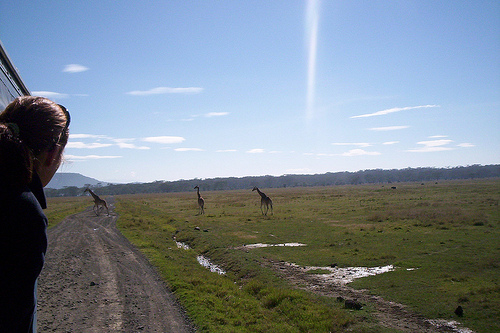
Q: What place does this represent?
A: It represents the field.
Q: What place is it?
A: It is a field.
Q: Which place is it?
A: It is a field.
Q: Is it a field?
A: Yes, it is a field.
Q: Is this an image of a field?
A: Yes, it is showing a field.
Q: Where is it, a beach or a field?
A: It is a field.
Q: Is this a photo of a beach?
A: No, the picture is showing a field.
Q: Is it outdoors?
A: Yes, it is outdoors.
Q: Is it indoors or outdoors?
A: It is outdoors.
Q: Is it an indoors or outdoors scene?
A: It is outdoors.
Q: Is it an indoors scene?
A: No, it is outdoors.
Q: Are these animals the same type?
A: Yes, all the animals are giraffes.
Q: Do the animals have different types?
A: No, all the animals are giraffes.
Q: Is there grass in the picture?
A: Yes, there is grass.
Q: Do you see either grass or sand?
A: Yes, there is grass.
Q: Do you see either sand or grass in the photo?
A: Yes, there is grass.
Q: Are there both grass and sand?
A: No, there is grass but no sand.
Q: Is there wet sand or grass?
A: Yes, there is wet grass.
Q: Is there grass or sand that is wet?
A: Yes, the grass is wet.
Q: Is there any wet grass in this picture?
A: Yes, there is wet grass.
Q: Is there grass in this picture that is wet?
A: Yes, there is grass that is wet.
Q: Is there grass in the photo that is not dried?
A: Yes, there is wet grass.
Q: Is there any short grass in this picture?
A: Yes, there is short grass.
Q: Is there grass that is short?
A: Yes, there is grass that is short.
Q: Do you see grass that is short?
A: Yes, there is grass that is short.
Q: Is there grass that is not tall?
A: Yes, there is short grass.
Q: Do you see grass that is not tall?
A: Yes, there is short grass.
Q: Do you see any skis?
A: No, there are no skis.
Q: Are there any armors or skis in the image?
A: No, there are no skis or armors.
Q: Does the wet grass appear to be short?
A: Yes, the grass is short.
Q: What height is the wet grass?
A: The grass is short.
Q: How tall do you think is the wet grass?
A: The grass is short.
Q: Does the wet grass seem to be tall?
A: No, the grass is short.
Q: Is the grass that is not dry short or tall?
A: The grass is short.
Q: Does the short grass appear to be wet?
A: Yes, the grass is wet.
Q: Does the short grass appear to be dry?
A: No, the grass is wet.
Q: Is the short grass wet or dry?
A: The grass is wet.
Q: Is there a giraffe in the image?
A: Yes, there is a giraffe.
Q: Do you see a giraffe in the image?
A: Yes, there is a giraffe.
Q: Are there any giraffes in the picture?
A: Yes, there is a giraffe.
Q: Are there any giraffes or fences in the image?
A: Yes, there is a giraffe.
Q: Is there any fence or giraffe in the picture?
A: Yes, there is a giraffe.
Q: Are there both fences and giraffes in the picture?
A: No, there is a giraffe but no fences.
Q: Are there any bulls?
A: No, there are no bulls.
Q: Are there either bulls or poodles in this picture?
A: No, there are no bulls or poodles.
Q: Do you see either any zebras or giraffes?
A: Yes, there is a giraffe.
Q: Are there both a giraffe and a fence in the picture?
A: No, there is a giraffe but no fences.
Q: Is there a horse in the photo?
A: No, there are no horses.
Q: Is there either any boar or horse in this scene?
A: No, there are no horses or boars.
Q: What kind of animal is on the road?
A: The animal is a giraffe.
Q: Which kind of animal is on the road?
A: The animal is a giraffe.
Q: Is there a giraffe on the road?
A: Yes, there is a giraffe on the road.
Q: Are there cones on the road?
A: No, there is a giraffe on the road.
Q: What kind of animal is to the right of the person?
A: The animal is a giraffe.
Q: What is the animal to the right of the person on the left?
A: The animal is a giraffe.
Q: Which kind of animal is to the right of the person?
A: The animal is a giraffe.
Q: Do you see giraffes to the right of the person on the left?
A: Yes, there is a giraffe to the right of the person.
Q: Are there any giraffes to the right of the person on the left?
A: Yes, there is a giraffe to the right of the person.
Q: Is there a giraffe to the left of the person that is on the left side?
A: No, the giraffe is to the right of the person.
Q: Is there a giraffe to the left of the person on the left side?
A: No, the giraffe is to the right of the person.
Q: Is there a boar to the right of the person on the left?
A: No, there is a giraffe to the right of the person.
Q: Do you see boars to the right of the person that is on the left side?
A: No, there is a giraffe to the right of the person.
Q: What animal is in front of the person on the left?
A: The giraffe is in front of the person.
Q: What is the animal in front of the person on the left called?
A: The animal is a giraffe.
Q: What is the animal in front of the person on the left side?
A: The animal is a giraffe.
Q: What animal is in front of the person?
A: The animal is a giraffe.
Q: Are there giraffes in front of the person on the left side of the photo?
A: Yes, there is a giraffe in front of the person.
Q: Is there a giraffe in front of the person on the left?
A: Yes, there is a giraffe in front of the person.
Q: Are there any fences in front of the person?
A: No, there is a giraffe in front of the person.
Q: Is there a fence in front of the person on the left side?
A: No, there is a giraffe in front of the person.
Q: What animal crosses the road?
A: The animal is a giraffe.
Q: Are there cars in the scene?
A: No, there are no cars.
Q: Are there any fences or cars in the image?
A: No, there are no cars or fences.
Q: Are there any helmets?
A: No, there are no helmets.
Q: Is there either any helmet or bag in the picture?
A: No, there are no helmets or bags.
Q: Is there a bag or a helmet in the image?
A: No, there are no helmets or bags.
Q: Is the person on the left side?
A: Yes, the person is on the left of the image.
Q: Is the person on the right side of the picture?
A: No, the person is on the left of the image.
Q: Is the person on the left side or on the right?
A: The person is on the left of the image.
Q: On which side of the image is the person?
A: The person is on the left of the image.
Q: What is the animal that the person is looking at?
A: The animal is a giraffe.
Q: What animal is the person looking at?
A: The person is looking at the giraffe.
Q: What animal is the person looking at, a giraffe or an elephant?
A: The person is looking at a giraffe.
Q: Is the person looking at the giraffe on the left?
A: Yes, the person is looking at the giraffe.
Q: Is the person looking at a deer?
A: No, the person is looking at the giraffe.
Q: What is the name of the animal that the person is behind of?
A: The animal is a giraffe.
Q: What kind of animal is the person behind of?
A: The person is behind the giraffe.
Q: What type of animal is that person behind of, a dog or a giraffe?
A: The person is behind a giraffe.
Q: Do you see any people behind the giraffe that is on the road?
A: Yes, there is a person behind the giraffe.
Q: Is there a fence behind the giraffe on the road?
A: No, there is a person behind the giraffe.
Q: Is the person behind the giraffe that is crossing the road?
A: Yes, the person is behind the giraffe.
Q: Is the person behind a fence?
A: No, the person is behind the giraffe.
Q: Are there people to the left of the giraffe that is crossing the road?
A: Yes, there is a person to the left of the giraffe.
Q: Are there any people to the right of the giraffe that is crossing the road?
A: No, the person is to the left of the giraffe.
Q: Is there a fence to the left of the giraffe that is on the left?
A: No, there is a person to the left of the giraffe.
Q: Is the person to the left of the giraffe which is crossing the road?
A: Yes, the person is to the left of the giraffe.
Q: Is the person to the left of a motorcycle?
A: No, the person is to the left of the giraffe.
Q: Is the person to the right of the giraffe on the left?
A: No, the person is to the left of the giraffe.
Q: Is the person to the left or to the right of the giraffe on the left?
A: The person is to the left of the giraffe.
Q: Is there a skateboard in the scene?
A: No, there are no skateboards.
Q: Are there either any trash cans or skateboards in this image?
A: No, there are no skateboards or trash cans.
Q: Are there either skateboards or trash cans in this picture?
A: No, there are no skateboards or trash cans.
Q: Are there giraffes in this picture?
A: Yes, there are giraffes.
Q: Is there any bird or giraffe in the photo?
A: Yes, there are giraffes.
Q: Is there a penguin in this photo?
A: No, there are no penguins.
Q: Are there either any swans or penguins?
A: No, there are no penguins or swans.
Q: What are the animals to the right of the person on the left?
A: The animals are giraffes.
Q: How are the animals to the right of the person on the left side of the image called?
A: The animals are giraffes.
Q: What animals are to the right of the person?
A: The animals are giraffes.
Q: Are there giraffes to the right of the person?
A: Yes, there are giraffes to the right of the person.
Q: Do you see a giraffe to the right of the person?
A: Yes, there are giraffes to the right of the person.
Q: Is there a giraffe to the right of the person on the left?
A: Yes, there are giraffes to the right of the person.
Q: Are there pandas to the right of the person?
A: No, there are giraffes to the right of the person.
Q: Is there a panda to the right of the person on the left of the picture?
A: No, there are giraffes to the right of the person.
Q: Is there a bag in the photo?
A: No, there are no bags.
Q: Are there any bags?
A: No, there are no bags.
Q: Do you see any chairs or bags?
A: No, there are no bags or chairs.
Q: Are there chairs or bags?
A: No, there are no bags or chairs.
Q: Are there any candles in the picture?
A: No, there are no candles.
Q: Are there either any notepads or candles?
A: No, there are no candles or notepads.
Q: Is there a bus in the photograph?
A: Yes, there is a bus.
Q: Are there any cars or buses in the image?
A: Yes, there is a bus.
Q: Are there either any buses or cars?
A: Yes, there is a bus.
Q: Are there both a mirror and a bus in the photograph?
A: No, there is a bus but no mirrors.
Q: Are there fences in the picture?
A: No, there are no fences.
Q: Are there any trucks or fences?
A: No, there are no fences or trucks.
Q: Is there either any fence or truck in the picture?
A: No, there are no fences or trucks.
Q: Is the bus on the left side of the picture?
A: Yes, the bus is on the left of the image.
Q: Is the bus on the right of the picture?
A: No, the bus is on the left of the image.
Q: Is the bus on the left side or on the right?
A: The bus is on the left of the image.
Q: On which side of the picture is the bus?
A: The bus is on the left of the image.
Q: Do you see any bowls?
A: No, there are no bowls.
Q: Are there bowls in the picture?
A: No, there are no bowls.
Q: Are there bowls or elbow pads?
A: No, there are no bowls or elbow pads.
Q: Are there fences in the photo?
A: No, there are no fences.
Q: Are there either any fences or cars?
A: No, there are no fences or cars.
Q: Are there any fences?
A: No, there are no fences.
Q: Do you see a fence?
A: No, there are no fences.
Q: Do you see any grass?
A: Yes, there is grass.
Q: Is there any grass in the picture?
A: Yes, there is grass.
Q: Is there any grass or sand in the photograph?
A: Yes, there is grass.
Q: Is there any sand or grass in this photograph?
A: Yes, there is grass.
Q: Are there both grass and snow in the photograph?
A: No, there is grass but no snow.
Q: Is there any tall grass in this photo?
A: Yes, there is tall grass.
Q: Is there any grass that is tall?
A: Yes, there is grass that is tall.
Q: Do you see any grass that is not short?
A: Yes, there is tall grass.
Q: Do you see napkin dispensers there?
A: No, there are no napkin dispensers.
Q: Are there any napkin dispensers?
A: No, there are no napkin dispensers.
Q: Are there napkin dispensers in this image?
A: No, there are no napkin dispensers.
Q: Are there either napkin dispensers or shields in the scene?
A: No, there are no napkin dispensers or shields.